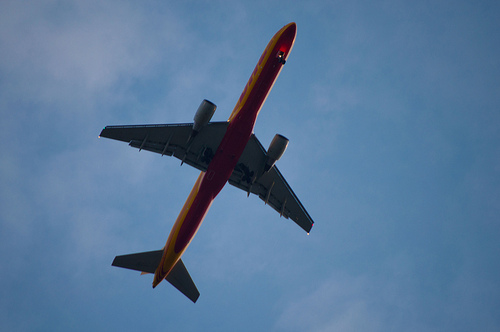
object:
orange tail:
[110, 195, 201, 306]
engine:
[189, 97, 216, 137]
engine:
[265, 127, 288, 175]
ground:
[376, 115, 432, 185]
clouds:
[0, 3, 458, 332]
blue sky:
[1, 0, 500, 332]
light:
[276, 52, 284, 67]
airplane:
[98, 21, 316, 303]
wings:
[112, 247, 167, 275]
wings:
[162, 258, 201, 304]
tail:
[110, 246, 200, 303]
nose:
[273, 22, 298, 49]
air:
[0, 0, 499, 331]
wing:
[82, 121, 232, 176]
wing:
[227, 129, 315, 238]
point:
[289, 19, 298, 29]